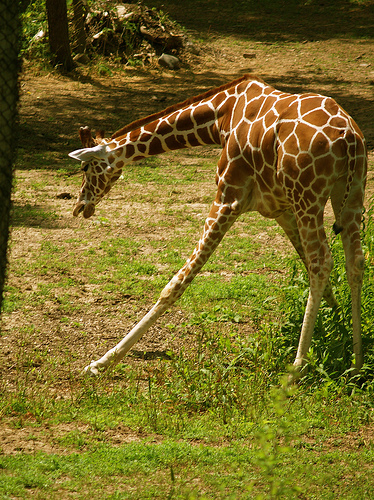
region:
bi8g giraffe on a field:
[60, 75, 366, 374]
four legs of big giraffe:
[75, 196, 363, 378]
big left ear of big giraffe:
[68, 145, 102, 167]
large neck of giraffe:
[118, 79, 225, 174]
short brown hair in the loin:
[110, 69, 258, 137]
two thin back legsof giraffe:
[286, 187, 367, 375]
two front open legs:
[84, 201, 341, 374]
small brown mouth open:
[70, 203, 93, 215]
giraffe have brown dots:
[64, 79, 372, 389]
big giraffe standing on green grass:
[63, 74, 363, 391]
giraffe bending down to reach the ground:
[61, 66, 373, 384]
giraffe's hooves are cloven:
[73, 352, 127, 380]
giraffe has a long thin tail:
[330, 125, 362, 239]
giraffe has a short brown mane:
[105, 68, 273, 147]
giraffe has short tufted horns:
[76, 122, 97, 147]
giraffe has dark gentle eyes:
[76, 158, 92, 175]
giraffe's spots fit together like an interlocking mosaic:
[206, 70, 365, 220]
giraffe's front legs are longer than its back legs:
[73, 150, 369, 381]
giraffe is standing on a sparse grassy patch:
[12, 224, 369, 495]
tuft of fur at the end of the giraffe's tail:
[327, 129, 366, 247]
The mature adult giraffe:
[72, 72, 368, 381]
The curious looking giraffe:
[68, 72, 366, 379]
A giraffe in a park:
[0, 0, 370, 496]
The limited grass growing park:
[0, 0, 370, 497]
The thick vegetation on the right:
[275, 194, 369, 393]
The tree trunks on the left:
[0, 0, 89, 300]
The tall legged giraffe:
[44, 71, 366, 378]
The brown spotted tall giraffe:
[69, 70, 360, 376]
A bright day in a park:
[0, 0, 367, 495]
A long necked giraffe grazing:
[72, 70, 360, 374]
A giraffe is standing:
[43, 68, 364, 401]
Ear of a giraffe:
[65, 143, 101, 166]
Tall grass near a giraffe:
[77, 263, 359, 437]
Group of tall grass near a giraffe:
[231, 301, 359, 382]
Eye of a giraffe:
[78, 165, 92, 178]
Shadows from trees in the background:
[32, 59, 115, 120]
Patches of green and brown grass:
[14, 403, 170, 493]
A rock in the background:
[156, 50, 184, 72]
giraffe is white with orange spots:
[40, 73, 371, 389]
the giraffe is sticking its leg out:
[60, 202, 248, 401]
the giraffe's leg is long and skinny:
[67, 195, 249, 401]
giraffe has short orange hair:
[84, 71, 266, 161]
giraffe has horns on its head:
[55, 115, 126, 222]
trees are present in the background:
[22, 0, 201, 84]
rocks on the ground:
[98, 36, 223, 83]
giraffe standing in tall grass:
[253, 246, 370, 419]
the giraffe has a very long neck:
[93, 76, 245, 190]